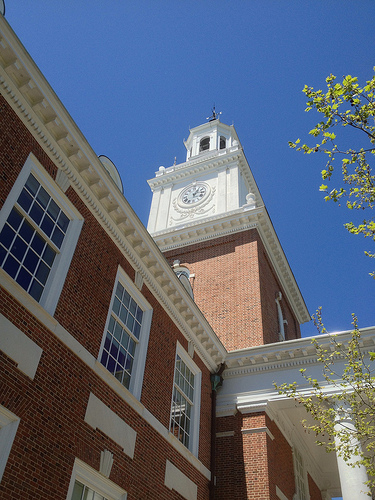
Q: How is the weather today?
A: It is cloudless.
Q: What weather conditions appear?
A: It is cloudless.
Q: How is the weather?
A: It is cloudless.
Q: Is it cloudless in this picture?
A: Yes, it is cloudless.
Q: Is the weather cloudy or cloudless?
A: It is cloudless.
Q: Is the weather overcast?
A: No, it is cloudless.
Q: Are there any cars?
A: No, there are no cars.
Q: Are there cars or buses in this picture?
A: No, there are no cars or buses.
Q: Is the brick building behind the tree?
A: Yes, the building is behind the tree.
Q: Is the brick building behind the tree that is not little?
A: Yes, the building is behind the tree.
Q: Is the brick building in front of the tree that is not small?
A: No, the building is behind the tree.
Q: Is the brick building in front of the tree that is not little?
A: No, the building is behind the tree.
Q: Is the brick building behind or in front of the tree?
A: The building is behind the tree.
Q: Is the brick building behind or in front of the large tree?
A: The building is behind the tree.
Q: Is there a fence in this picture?
A: No, there are no fences.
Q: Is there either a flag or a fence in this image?
A: No, there are no fences or flags.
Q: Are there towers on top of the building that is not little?
A: Yes, there is a tower on top of the building.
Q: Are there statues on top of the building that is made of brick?
A: No, there is a tower on top of the building.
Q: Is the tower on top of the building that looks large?
A: Yes, the tower is on top of the building.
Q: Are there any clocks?
A: Yes, there is a clock.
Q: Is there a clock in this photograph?
A: Yes, there is a clock.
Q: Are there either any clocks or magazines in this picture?
A: Yes, there is a clock.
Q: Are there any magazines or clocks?
A: Yes, there is a clock.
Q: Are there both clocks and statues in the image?
A: No, there is a clock but no statues.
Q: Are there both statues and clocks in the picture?
A: No, there is a clock but no statues.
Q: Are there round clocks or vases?
A: Yes, there is a round clock.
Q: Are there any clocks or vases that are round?
A: Yes, the clock is round.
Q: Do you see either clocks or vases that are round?
A: Yes, the clock is round.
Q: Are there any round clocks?
A: Yes, there is a round clock.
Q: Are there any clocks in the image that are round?
A: Yes, there is a clock that is round.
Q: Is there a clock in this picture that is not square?
A: Yes, there is a round clock.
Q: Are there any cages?
A: No, there are no cages.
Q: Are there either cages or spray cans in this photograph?
A: No, there are no cages or spray cans.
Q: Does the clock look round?
A: Yes, the clock is round.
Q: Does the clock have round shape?
A: Yes, the clock is round.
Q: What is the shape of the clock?
A: The clock is round.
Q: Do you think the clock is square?
A: No, the clock is round.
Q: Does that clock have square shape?
A: No, the clock is round.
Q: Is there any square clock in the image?
A: No, there is a clock but it is round.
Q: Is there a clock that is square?
A: No, there is a clock but it is round.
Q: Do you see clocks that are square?
A: No, there is a clock but it is round.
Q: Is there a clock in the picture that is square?
A: No, there is a clock but it is round.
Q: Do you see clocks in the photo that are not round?
A: No, there is a clock but it is round.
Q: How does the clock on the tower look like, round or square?
A: The clock is round.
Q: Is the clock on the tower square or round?
A: The clock is round.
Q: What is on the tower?
A: The clock is on the tower.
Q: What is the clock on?
A: The clock is on the tower.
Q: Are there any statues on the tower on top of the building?
A: No, there is a clock on the tower.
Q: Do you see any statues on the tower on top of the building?
A: No, there is a clock on the tower.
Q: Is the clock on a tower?
A: Yes, the clock is on a tower.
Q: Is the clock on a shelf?
A: No, the clock is on a tower.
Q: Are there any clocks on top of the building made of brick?
A: Yes, there is a clock on top of the building.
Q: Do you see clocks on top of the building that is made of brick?
A: Yes, there is a clock on top of the building.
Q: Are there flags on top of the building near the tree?
A: No, there is a clock on top of the building.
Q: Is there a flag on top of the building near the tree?
A: No, there is a clock on top of the building.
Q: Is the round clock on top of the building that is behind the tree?
A: Yes, the clock is on top of the building.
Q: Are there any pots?
A: No, there are no pots.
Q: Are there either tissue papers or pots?
A: No, there are no pots or tissue papers.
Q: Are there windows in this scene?
A: Yes, there is a window.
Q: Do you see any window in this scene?
A: Yes, there is a window.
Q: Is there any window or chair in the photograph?
A: Yes, there is a window.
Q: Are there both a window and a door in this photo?
A: No, there is a window but no doors.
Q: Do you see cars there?
A: No, there are no cars.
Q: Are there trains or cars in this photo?
A: No, there are no cars or trains.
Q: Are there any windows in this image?
A: Yes, there is a window.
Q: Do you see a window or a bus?
A: Yes, there is a window.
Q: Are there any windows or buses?
A: Yes, there is a window.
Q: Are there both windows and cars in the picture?
A: No, there is a window but no cars.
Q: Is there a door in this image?
A: No, there are no doors.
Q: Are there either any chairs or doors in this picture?
A: No, there are no doors or chairs.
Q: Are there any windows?
A: Yes, there is a window.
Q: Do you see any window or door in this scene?
A: Yes, there is a window.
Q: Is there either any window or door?
A: Yes, there is a window.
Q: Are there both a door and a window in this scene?
A: No, there is a window but no doors.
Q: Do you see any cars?
A: No, there are no cars.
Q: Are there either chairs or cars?
A: No, there are no cars or chairs.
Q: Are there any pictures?
A: No, there are no pictures.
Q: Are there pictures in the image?
A: No, there are no pictures.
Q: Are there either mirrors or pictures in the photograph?
A: No, there are no pictures or mirrors.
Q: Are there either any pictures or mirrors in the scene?
A: No, there are no pictures or mirrors.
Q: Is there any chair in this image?
A: No, there are no chairs.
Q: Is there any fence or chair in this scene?
A: No, there are no chairs or fences.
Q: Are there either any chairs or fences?
A: No, there are no chairs or fences.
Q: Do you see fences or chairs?
A: No, there are no chairs or fences.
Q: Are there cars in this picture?
A: No, there are no cars.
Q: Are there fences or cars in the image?
A: No, there are no cars or fences.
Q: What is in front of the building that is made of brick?
A: The tree is in front of the building.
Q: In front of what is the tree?
A: The tree is in front of the building.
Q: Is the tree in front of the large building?
A: Yes, the tree is in front of the building.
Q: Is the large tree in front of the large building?
A: Yes, the tree is in front of the building.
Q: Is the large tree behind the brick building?
A: No, the tree is in front of the building.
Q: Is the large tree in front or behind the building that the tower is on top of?
A: The tree is in front of the building.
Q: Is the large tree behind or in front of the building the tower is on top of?
A: The tree is in front of the building.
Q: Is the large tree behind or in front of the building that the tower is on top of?
A: The tree is in front of the building.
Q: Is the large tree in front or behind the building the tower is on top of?
A: The tree is in front of the building.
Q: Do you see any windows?
A: Yes, there is a window.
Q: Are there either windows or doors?
A: Yes, there is a window.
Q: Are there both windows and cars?
A: No, there is a window but no cars.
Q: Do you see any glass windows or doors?
A: Yes, there is a glass window.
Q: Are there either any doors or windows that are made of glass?
A: Yes, the window is made of glass.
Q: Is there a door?
A: No, there are no doors.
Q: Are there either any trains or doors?
A: No, there are no doors or trains.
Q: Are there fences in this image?
A: No, there are no fences.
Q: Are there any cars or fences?
A: No, there are no fences or cars.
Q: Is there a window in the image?
A: Yes, there is a window.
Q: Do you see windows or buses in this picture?
A: Yes, there is a window.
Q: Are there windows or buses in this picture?
A: Yes, there is a window.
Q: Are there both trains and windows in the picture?
A: No, there is a window but no trains.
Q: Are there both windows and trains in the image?
A: No, there is a window but no trains.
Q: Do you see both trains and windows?
A: No, there is a window but no trains.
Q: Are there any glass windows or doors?
A: Yes, there is a glass window.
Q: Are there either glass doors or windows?
A: Yes, there is a glass window.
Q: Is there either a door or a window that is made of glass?
A: Yes, the window is made of glass.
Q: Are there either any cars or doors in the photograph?
A: No, there are no cars or doors.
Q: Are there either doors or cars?
A: No, there are no cars or doors.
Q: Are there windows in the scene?
A: Yes, there is a window.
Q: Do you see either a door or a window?
A: Yes, there is a window.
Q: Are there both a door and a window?
A: No, there is a window but no doors.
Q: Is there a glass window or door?
A: Yes, there is a glass window.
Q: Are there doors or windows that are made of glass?
A: Yes, the window is made of glass.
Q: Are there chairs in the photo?
A: No, there are no chairs.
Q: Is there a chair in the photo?
A: No, there are no chairs.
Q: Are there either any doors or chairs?
A: No, there are no chairs or doors.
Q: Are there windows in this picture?
A: Yes, there is a window.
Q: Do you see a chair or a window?
A: Yes, there is a window.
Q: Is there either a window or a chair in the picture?
A: Yes, there is a window.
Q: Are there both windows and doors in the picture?
A: No, there is a window but no doors.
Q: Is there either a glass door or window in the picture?
A: Yes, there is a glass window.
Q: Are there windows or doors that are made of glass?
A: Yes, the window is made of glass.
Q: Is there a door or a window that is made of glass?
A: Yes, the window is made of glass.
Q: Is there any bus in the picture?
A: No, there are no buses.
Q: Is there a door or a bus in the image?
A: No, there are no buses or doors.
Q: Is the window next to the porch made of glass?
A: Yes, the window is made of glass.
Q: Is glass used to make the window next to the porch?
A: Yes, the window is made of glass.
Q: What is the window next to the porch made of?
A: The window is made of glass.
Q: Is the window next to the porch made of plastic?
A: No, the window is made of glass.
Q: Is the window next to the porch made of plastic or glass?
A: The window is made of glass.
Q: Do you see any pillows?
A: No, there are no pillows.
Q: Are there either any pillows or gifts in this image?
A: No, there are no pillows or gifts.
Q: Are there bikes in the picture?
A: No, there are no bikes.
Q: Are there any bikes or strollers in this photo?
A: No, there are no bikes or strollers.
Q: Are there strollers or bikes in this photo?
A: No, there are no bikes or strollers.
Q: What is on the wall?
A: The decoration is on the wall.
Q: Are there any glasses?
A: No, there are no glasses.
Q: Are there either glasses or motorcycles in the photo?
A: No, there are no glasses or motorcycles.